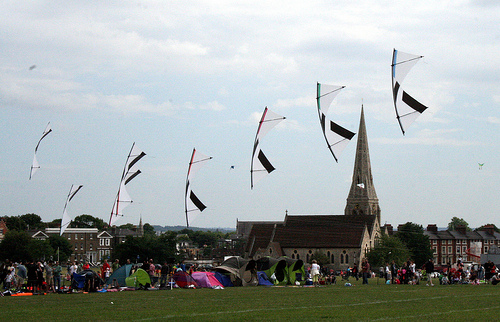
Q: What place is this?
A: It is a city.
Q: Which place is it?
A: It is a city.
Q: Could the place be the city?
A: Yes, it is the city.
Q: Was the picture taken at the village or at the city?
A: It was taken at the city.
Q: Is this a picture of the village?
A: No, the picture is showing the city.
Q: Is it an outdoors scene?
A: Yes, it is outdoors.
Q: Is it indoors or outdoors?
A: It is outdoors.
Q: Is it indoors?
A: No, it is outdoors.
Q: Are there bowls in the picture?
A: No, there are no bowls.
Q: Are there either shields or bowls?
A: No, there are no bowls or shields.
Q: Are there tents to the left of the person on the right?
A: Yes, there is a tent to the left of the person.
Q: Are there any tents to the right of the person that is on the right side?
A: No, the tent is to the left of the person.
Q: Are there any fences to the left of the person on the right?
A: No, there is a tent to the left of the person.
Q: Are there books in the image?
A: No, there are no books.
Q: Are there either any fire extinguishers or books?
A: No, there are no books or fire extinguishers.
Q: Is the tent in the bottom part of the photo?
A: Yes, the tent is in the bottom of the image.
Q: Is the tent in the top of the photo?
A: No, the tent is in the bottom of the image.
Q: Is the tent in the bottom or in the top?
A: The tent is in the bottom of the image.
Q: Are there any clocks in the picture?
A: No, there are no clocks.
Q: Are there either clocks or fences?
A: No, there are no clocks or fences.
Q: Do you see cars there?
A: No, there are no cars.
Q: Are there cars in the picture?
A: No, there are no cars.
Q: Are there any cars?
A: No, there are no cars.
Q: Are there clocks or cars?
A: No, there are no cars or clocks.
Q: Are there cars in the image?
A: No, there are no cars.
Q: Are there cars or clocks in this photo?
A: No, there are no cars or clocks.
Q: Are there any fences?
A: No, there are no fences.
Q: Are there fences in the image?
A: No, there are no fences.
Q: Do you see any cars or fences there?
A: No, there are no fences or cars.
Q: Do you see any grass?
A: Yes, there is grass.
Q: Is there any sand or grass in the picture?
A: Yes, there is grass.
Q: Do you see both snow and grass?
A: No, there is grass but no snow.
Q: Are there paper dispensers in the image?
A: No, there are no paper dispensers.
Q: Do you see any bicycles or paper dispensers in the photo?
A: No, there are no paper dispensers or bicycles.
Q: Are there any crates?
A: No, there are no crates.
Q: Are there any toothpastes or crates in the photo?
A: No, there are no crates or toothpastes.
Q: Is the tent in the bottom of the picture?
A: Yes, the tent is in the bottom of the image.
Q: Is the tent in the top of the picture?
A: No, the tent is in the bottom of the image.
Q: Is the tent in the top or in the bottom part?
A: The tent is in the bottom of the image.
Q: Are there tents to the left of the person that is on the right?
A: Yes, there is a tent to the left of the person.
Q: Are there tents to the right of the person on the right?
A: No, the tent is to the left of the person.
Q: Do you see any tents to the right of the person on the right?
A: No, the tent is to the left of the person.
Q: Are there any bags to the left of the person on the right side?
A: No, there is a tent to the left of the person.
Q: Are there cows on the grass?
A: No, there is a tent on the grass.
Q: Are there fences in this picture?
A: No, there are no fences.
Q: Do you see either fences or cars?
A: No, there are no fences or cars.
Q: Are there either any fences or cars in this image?
A: No, there are no fences or cars.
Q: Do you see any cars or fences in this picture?
A: No, there are no fences or cars.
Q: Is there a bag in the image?
A: No, there are no bags.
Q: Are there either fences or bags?
A: No, there are no bags or fences.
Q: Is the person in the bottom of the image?
A: Yes, the person is in the bottom of the image.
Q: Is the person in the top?
A: No, the person is in the bottom of the image.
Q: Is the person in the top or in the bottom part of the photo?
A: The person is in the bottom of the image.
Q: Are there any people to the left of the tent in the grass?
A: No, the person is to the right of the tent.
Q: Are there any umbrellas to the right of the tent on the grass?
A: No, there is a person to the right of the tent.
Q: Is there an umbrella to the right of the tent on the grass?
A: No, there is a person to the right of the tent.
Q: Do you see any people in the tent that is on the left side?
A: Yes, there is a person in the tent.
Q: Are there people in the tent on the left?
A: Yes, there is a person in the tent.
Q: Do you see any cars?
A: No, there are no cars.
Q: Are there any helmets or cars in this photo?
A: No, there are no cars or helmets.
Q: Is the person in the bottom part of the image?
A: Yes, the person is in the bottom of the image.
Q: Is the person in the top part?
A: No, the person is in the bottom of the image.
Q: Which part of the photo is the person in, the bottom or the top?
A: The person is in the bottom of the image.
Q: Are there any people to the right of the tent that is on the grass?
A: Yes, there is a person to the right of the tent.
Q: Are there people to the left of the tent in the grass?
A: No, the person is to the right of the tent.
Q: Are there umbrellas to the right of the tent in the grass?
A: No, there is a person to the right of the tent.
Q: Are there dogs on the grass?
A: No, there is a person on the grass.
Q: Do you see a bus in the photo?
A: No, there are no buses.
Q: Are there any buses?
A: No, there are no buses.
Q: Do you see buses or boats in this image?
A: No, there are no buses or boats.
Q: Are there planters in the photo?
A: No, there are no planters.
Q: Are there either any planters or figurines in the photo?
A: No, there are no planters or figurines.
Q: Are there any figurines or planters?
A: No, there are no planters or figurines.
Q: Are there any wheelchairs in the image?
A: No, there are no wheelchairs.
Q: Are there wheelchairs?
A: No, there are no wheelchairs.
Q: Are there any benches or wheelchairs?
A: No, there are no wheelchairs or benches.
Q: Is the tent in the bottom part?
A: Yes, the tent is in the bottom of the image.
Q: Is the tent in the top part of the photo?
A: No, the tent is in the bottom of the image.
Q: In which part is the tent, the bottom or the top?
A: The tent is in the bottom of the image.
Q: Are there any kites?
A: Yes, there is a kite.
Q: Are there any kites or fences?
A: Yes, there is a kite.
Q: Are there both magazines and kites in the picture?
A: No, there is a kite but no magazines.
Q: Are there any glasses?
A: No, there are no glasses.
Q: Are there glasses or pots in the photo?
A: No, there are no glasses or pots.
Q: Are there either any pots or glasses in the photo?
A: No, there are no glasses or pots.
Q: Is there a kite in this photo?
A: Yes, there is a kite.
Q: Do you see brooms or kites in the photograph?
A: Yes, there is a kite.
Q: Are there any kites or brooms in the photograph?
A: Yes, there is a kite.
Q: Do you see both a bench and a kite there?
A: No, there is a kite but no benches.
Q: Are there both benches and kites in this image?
A: No, there is a kite but no benches.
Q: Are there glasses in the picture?
A: No, there are no glasses.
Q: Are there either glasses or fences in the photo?
A: No, there are no glasses or fences.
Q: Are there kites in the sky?
A: Yes, there is a kite in the sky.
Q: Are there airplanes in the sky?
A: No, there is a kite in the sky.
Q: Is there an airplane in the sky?
A: No, there is a kite in the sky.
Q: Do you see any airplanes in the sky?
A: No, there is a kite in the sky.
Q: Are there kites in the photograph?
A: Yes, there is a kite.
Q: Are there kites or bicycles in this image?
A: Yes, there is a kite.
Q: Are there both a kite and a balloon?
A: No, there is a kite but no balloons.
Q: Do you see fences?
A: No, there are no fences.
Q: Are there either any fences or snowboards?
A: No, there are no fences or snowboards.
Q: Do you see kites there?
A: Yes, there is a kite.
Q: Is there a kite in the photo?
A: Yes, there is a kite.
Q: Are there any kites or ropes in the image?
A: Yes, there is a kite.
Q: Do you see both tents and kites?
A: Yes, there are both a kite and a tent.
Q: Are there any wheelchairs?
A: No, there are no wheelchairs.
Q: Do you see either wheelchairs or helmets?
A: No, there are no wheelchairs or helmets.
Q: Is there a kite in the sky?
A: Yes, there is a kite in the sky.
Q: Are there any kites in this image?
A: Yes, there is a kite.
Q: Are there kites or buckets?
A: Yes, there is a kite.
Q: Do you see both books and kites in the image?
A: No, there is a kite but no books.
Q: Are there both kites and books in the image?
A: No, there is a kite but no books.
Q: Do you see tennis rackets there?
A: No, there are no tennis rackets.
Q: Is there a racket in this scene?
A: No, there are no rackets.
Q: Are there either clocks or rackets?
A: No, there are no rackets or clocks.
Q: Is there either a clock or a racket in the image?
A: No, there are no rackets or clocks.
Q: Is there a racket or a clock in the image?
A: No, there are no rackets or clocks.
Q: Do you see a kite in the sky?
A: Yes, there is a kite in the sky.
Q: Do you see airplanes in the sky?
A: No, there is a kite in the sky.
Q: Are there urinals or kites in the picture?
A: Yes, there is a kite.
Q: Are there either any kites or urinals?
A: Yes, there is a kite.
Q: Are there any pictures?
A: No, there are no pictures.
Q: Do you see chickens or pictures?
A: No, there are no pictures or chickens.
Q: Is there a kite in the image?
A: Yes, there is a kite.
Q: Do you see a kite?
A: Yes, there is a kite.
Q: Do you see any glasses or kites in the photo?
A: Yes, there is a kite.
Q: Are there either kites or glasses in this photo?
A: Yes, there is a kite.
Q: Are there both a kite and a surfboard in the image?
A: No, there is a kite but no surfboards.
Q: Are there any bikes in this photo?
A: No, there are no bikes.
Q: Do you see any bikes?
A: No, there are no bikes.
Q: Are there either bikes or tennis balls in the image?
A: No, there are no bikes or tennis balls.